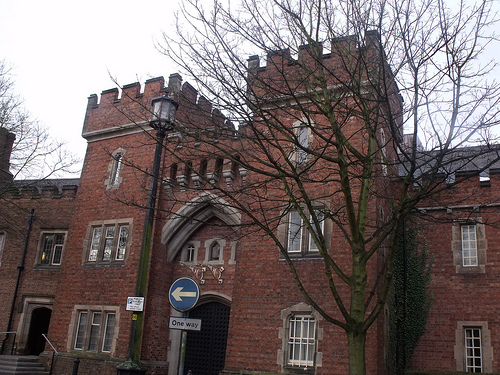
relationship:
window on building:
[84, 310, 106, 355] [3, 30, 497, 373]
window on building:
[73, 310, 113, 356] [3, 30, 497, 373]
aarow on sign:
[172, 282, 195, 304] [159, 272, 212, 314]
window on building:
[277, 307, 319, 373] [3, 30, 497, 373]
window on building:
[461, 323, 481, 373] [44, 97, 475, 349]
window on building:
[460, 221, 479, 266] [3, 30, 497, 373]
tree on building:
[225, 30, 455, 358] [3, 30, 497, 373]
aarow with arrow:
[168, 278, 199, 312] [168, 286, 197, 306]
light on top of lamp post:
[142, 89, 201, 139] [115, 131, 169, 372]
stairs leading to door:
[0, 352, 48, 374] [23, 303, 56, 357]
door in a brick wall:
[23, 303, 56, 357] [16, 198, 79, 355]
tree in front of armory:
[89, 0, 499, 375] [1, 30, 498, 373]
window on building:
[284, 200, 323, 252] [46, 31, 460, 366]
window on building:
[455, 222, 482, 273] [46, 31, 460, 366]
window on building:
[277, 304, 319, 371] [46, 31, 460, 366]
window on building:
[85, 220, 129, 262] [46, 31, 460, 366]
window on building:
[73, 310, 113, 356] [46, 31, 460, 366]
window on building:
[281, 200, 327, 258] [3, 30, 497, 373]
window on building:
[208, 242, 218, 261] [3, 30, 497, 373]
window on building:
[85, 217, 128, 262] [83, 105, 149, 271]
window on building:
[461, 323, 481, 373] [3, 30, 497, 373]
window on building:
[100, 143, 128, 188] [3, 30, 497, 373]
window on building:
[208, 239, 222, 261] [3, 30, 497, 373]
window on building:
[85, 217, 128, 262] [3, 30, 497, 373]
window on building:
[182, 241, 194, 261] [3, 30, 497, 373]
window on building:
[291, 117, 314, 166] [55, 53, 487, 345]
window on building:
[276, 117, 322, 167] [3, 30, 497, 373]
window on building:
[103, 147, 128, 187] [3, 30, 497, 373]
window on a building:
[85, 217, 128, 262] [34, 26, 375, 373]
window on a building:
[73, 310, 113, 356] [3, 30, 497, 373]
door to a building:
[23, 303, 56, 357] [89, 171, 338, 362]